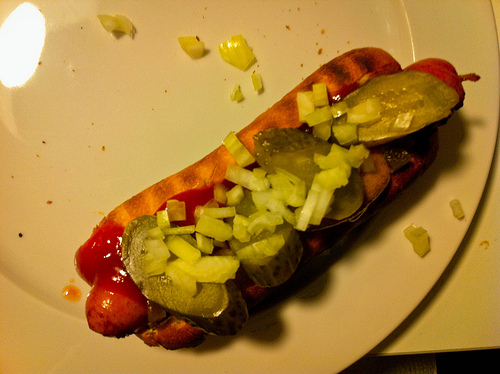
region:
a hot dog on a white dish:
[56, 42, 489, 352]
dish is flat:
[0, 1, 495, 367]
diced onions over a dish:
[85, 7, 267, 98]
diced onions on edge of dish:
[397, 195, 467, 260]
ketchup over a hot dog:
[72, 215, 153, 340]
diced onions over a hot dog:
[151, 82, 366, 285]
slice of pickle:
[336, 65, 461, 145]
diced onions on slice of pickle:
[121, 202, 236, 318]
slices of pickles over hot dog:
[116, 65, 446, 321]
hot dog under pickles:
[410, 46, 490, 111]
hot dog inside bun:
[41, 66, 448, 336]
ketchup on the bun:
[61, 204, 266, 307]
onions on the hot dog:
[140, 81, 390, 269]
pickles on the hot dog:
[287, 52, 446, 137]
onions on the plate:
[86, 8, 277, 123]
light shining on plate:
[3, 3, 75, 96]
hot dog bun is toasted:
[53, 65, 451, 350]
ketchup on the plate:
[52, 284, 95, 311]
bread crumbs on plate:
[4, 114, 139, 255]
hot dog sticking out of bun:
[55, 251, 141, 338]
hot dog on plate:
[66, 48, 433, 332]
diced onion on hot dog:
[205, 253, 246, 279]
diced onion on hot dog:
[198, 220, 237, 240]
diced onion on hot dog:
[268, 194, 302, 221]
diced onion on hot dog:
[302, 201, 323, 226]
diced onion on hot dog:
[170, 240, 197, 269]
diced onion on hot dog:
[336, 105, 377, 122]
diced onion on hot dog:
[238, 172, 270, 190]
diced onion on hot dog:
[250, 216, 270, 234]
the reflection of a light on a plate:
[0, 2, 47, 85]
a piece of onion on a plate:
[220, 32, 252, 67]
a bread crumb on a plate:
[317, 48, 322, 54]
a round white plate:
[0, 2, 497, 371]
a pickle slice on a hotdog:
[337, 74, 455, 138]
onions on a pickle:
[296, 144, 367, 230]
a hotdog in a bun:
[82, 279, 151, 333]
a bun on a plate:
[98, 46, 433, 347]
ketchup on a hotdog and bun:
[74, 222, 147, 303]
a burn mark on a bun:
[322, 61, 350, 82]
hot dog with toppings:
[66, 42, 488, 319]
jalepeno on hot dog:
[341, 78, 455, 125]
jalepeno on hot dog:
[263, 136, 352, 217]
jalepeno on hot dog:
[243, 205, 290, 280]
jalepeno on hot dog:
[131, 219, 244, 321]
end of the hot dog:
[67, 270, 142, 329]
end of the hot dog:
[420, 53, 469, 105]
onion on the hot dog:
[186, 258, 243, 278]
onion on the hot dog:
[297, 188, 342, 215]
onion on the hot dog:
[241, 174, 266, 194]